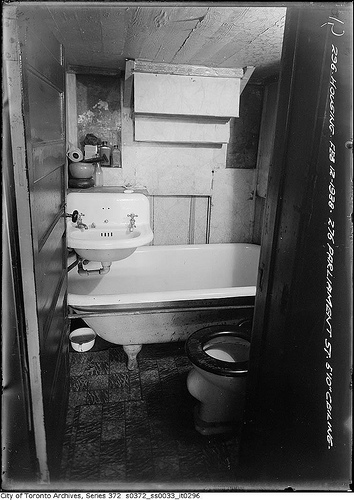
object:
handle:
[67, 208, 81, 224]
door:
[4, 16, 69, 486]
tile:
[87, 363, 107, 374]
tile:
[76, 359, 88, 375]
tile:
[88, 373, 106, 391]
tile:
[90, 375, 109, 387]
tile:
[107, 375, 126, 386]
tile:
[98, 377, 116, 396]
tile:
[88, 376, 107, 386]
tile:
[83, 390, 109, 406]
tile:
[107, 388, 124, 401]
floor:
[58, 368, 187, 484]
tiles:
[97, 440, 127, 483]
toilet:
[184, 370, 239, 436]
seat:
[185, 325, 262, 378]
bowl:
[69, 327, 96, 355]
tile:
[91, 423, 126, 447]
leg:
[122, 342, 145, 370]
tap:
[64, 210, 88, 230]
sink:
[66, 192, 154, 249]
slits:
[100, 230, 114, 237]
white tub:
[64, 243, 268, 370]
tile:
[89, 381, 111, 391]